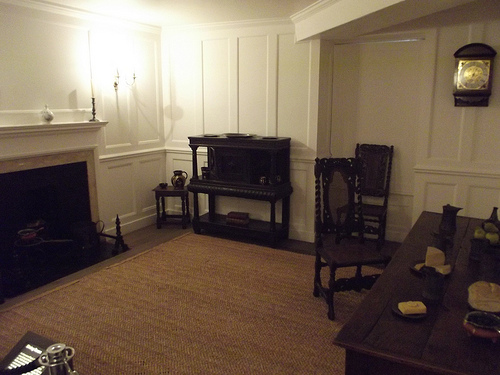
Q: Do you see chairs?
A: Yes, there is a chair.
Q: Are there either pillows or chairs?
A: Yes, there is a chair.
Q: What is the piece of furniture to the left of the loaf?
A: The piece of furniture is a chair.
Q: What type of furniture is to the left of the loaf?
A: The piece of furniture is a chair.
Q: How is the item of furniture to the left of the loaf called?
A: The piece of furniture is a chair.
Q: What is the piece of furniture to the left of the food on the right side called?
A: The piece of furniture is a chair.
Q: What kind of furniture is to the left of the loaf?
A: The piece of furniture is a chair.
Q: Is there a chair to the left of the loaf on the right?
A: Yes, there is a chair to the left of the loaf.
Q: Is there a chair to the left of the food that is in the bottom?
A: Yes, there is a chair to the left of the loaf.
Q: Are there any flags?
A: No, there are no flags.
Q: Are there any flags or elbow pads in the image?
A: No, there are no flags or elbow pads.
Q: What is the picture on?
A: The picture is on the table.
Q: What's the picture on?
A: The picture is on the table.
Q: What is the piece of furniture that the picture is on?
A: The piece of furniture is a table.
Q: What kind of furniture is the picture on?
A: The picture is on the table.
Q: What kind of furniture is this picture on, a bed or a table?
A: The picture is on a table.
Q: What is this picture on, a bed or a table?
A: The picture is on a table.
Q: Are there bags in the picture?
A: No, there are no bags.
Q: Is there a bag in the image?
A: No, there are no bags.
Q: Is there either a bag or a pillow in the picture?
A: No, there are no bags or pillows.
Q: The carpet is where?
A: The carpet is on the floor.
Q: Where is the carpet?
A: The carpet is on the floor.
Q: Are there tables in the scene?
A: Yes, there is a table.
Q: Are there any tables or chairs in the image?
A: Yes, there is a table.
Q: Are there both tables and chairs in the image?
A: Yes, there are both a table and a chair.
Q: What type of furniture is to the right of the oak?
A: The piece of furniture is a table.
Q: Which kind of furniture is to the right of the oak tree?
A: The piece of furniture is a table.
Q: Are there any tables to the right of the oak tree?
A: Yes, there is a table to the right of the oak tree.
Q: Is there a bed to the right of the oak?
A: No, there is a table to the right of the oak.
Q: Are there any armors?
A: No, there are no armors.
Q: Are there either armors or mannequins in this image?
A: No, there are no armors or mannequins.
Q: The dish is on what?
A: The dish is on the table.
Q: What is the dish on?
A: The dish is on the table.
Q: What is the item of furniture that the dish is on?
A: The piece of furniture is a table.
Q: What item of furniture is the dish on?
A: The dish is on the table.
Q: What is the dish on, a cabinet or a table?
A: The dish is on a table.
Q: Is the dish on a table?
A: Yes, the dish is on a table.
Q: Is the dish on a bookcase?
A: No, the dish is on a table.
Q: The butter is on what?
A: The butter is on the table.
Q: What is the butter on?
A: The butter is on the table.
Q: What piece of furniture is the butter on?
A: The butter is on the table.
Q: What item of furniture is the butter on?
A: The butter is on the table.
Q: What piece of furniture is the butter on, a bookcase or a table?
A: The butter is on a table.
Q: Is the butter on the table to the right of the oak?
A: Yes, the butter is on the table.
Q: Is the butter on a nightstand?
A: No, the butter is on the table.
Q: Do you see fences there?
A: No, there are no fences.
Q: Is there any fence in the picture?
A: No, there are no fences.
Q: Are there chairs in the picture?
A: Yes, there is a chair.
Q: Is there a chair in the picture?
A: Yes, there is a chair.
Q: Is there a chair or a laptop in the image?
A: Yes, there is a chair.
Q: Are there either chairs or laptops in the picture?
A: Yes, there is a chair.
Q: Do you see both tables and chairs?
A: Yes, there are both a chair and a table.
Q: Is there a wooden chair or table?
A: Yes, there is a wood chair.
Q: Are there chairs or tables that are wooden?
A: Yes, the chair is wooden.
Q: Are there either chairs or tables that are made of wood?
A: Yes, the chair is made of wood.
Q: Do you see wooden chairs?
A: Yes, there is a wood chair.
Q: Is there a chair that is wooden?
A: Yes, there is a chair that is wooden.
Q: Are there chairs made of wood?
A: Yes, there is a chair that is made of wood.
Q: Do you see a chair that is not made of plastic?
A: Yes, there is a chair that is made of wood.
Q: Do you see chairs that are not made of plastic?
A: Yes, there is a chair that is made of wood.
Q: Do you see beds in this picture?
A: No, there are no beds.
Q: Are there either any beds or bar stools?
A: No, there are no beds or bar stools.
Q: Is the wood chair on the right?
A: Yes, the chair is on the right of the image.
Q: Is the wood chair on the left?
A: No, the chair is on the right of the image.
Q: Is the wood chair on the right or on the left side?
A: The chair is on the right of the image.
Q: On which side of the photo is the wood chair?
A: The chair is on the right of the image.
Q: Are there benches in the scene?
A: No, there are no benches.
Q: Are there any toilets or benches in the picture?
A: No, there are no benches or toilets.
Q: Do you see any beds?
A: No, there are no beds.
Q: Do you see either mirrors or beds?
A: No, there are no beds or mirrors.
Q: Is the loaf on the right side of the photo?
A: Yes, the loaf is on the right of the image.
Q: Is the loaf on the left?
A: No, the loaf is on the right of the image.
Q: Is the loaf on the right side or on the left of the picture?
A: The loaf is on the right of the image.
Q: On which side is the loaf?
A: The loaf is on the right of the image.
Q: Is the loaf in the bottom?
A: Yes, the loaf is in the bottom of the image.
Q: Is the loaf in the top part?
A: No, the loaf is in the bottom of the image.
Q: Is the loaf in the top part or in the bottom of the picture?
A: The loaf is in the bottom of the image.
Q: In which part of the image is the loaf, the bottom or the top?
A: The loaf is in the bottom of the image.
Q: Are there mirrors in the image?
A: No, there are no mirrors.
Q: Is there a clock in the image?
A: Yes, there is a clock.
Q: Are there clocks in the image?
A: Yes, there is a clock.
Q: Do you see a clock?
A: Yes, there is a clock.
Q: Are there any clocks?
A: Yes, there is a clock.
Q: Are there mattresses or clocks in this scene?
A: Yes, there is a clock.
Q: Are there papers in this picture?
A: No, there are no papers.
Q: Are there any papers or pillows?
A: No, there are no papers or pillows.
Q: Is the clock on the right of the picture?
A: Yes, the clock is on the right of the image.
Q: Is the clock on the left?
A: No, the clock is on the right of the image.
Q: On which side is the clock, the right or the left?
A: The clock is on the right of the image.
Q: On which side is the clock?
A: The clock is on the right of the image.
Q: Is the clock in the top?
A: Yes, the clock is in the top of the image.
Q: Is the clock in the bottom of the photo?
A: No, the clock is in the top of the image.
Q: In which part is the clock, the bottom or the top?
A: The clock is in the top of the image.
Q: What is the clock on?
A: The clock is on the wall.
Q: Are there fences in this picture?
A: No, there are no fences.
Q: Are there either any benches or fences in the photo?
A: No, there are no fences or benches.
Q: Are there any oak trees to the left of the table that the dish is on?
A: Yes, there is an oak tree to the left of the table.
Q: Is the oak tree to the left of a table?
A: Yes, the oak tree is to the left of a table.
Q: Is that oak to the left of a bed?
A: No, the oak is to the left of a table.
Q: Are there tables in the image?
A: Yes, there is a table.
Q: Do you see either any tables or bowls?
A: Yes, there is a table.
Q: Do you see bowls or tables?
A: Yes, there is a table.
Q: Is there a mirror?
A: No, there are no mirrors.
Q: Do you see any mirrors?
A: No, there are no mirrors.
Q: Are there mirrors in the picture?
A: No, there are no mirrors.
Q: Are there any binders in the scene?
A: No, there are no binders.